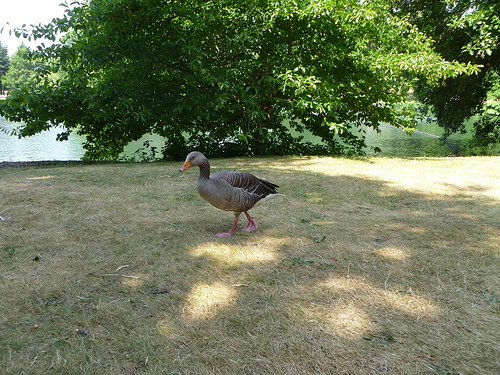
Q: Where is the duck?
A: On grass.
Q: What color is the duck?
A: Gray.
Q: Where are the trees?
A: Beside water.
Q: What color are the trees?
A: Green.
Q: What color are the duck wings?
A: Black.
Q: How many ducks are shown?
A: One.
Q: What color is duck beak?
A: Orange.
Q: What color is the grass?
A: Tan.